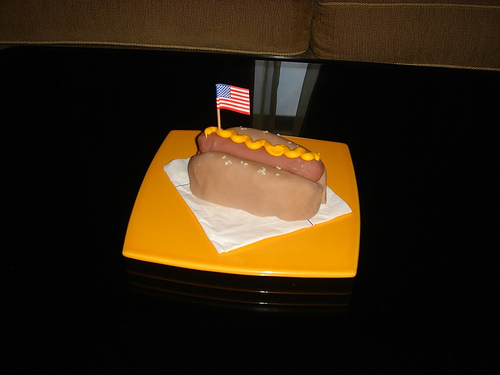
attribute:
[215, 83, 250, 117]
flag — american, tiny, small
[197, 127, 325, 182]
hot dog — dessert, cake, pink, rounded, fake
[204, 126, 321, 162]
mustard — yellow, swirly, frosting, fake, swirled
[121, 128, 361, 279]
plate — bright yellow, yellow, square, somewhat orange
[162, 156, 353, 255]
napkin — white, paper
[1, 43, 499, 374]
surface — shiny, black, table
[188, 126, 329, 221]
hot dog bun — light brown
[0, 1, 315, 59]
cushion — part of couch, part of sofa, brown, furniture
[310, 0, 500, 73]
cushion — part of couch, part of sofa, brown, couch edge, furniture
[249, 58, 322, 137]
window — white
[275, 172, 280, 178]
sesame seed — fake, white, small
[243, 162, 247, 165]
sesame seed — fake, small, white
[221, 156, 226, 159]
sesame seed — fake, white, small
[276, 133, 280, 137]
sesame seed — white, small, fake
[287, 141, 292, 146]
sesame seed — white, small, fake